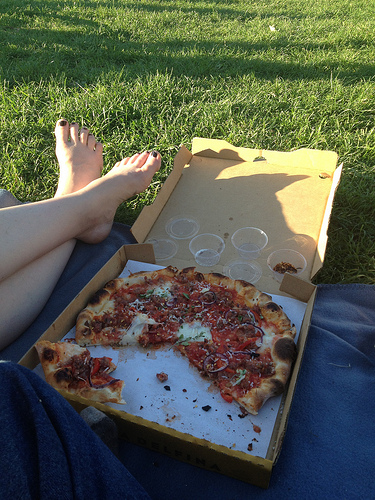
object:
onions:
[216, 329, 259, 351]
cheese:
[179, 324, 210, 342]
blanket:
[0, 187, 374, 497]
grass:
[1, 5, 372, 160]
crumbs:
[155, 370, 262, 452]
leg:
[0, 246, 58, 353]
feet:
[74, 150, 161, 246]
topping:
[101, 279, 271, 404]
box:
[15, 136, 344, 489]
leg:
[1, 202, 47, 283]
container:
[144, 211, 306, 286]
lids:
[128, 135, 344, 280]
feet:
[53, 119, 103, 200]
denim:
[0, 360, 149, 500]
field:
[0, 0, 375, 498]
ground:
[2, 2, 374, 494]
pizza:
[34, 265, 297, 417]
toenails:
[151, 151, 159, 159]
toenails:
[59, 120, 67, 128]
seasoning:
[273, 260, 298, 274]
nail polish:
[59, 120, 68, 127]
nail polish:
[150, 151, 158, 158]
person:
[0, 358, 146, 499]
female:
[0, 119, 162, 354]